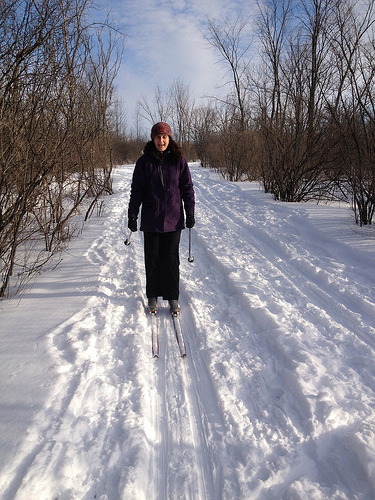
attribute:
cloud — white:
[64, 3, 297, 132]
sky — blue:
[1, 1, 370, 146]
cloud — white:
[112, 7, 236, 130]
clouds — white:
[91, 1, 374, 139]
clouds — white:
[84, 2, 277, 133]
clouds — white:
[126, 20, 226, 83]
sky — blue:
[94, 7, 309, 90]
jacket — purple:
[132, 154, 196, 242]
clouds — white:
[215, 7, 248, 35]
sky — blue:
[60, 3, 313, 111]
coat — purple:
[127, 142, 199, 234]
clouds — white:
[95, 6, 232, 106]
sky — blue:
[94, 1, 369, 125]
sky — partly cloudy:
[7, 10, 369, 126]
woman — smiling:
[148, 124, 187, 158]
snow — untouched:
[241, 212, 373, 319]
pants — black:
[142, 225, 182, 302]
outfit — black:
[121, 140, 200, 300]